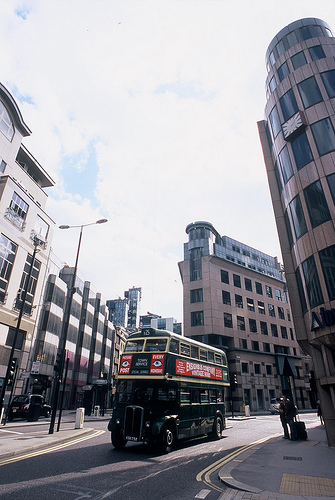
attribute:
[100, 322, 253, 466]
bus — dark green, double-decker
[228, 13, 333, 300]
building — tall 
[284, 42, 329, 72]
windows —  lots 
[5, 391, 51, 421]
car — old, black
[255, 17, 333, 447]
building — very tall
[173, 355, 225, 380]
sign — red, white